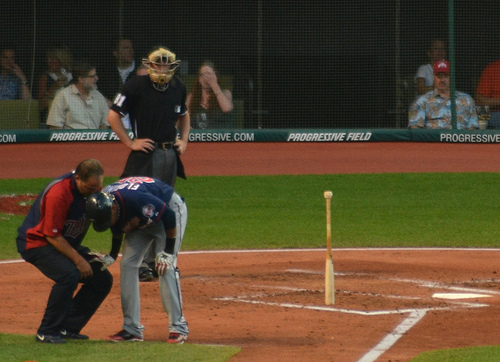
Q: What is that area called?
A: Baseball diamond.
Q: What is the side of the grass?
A: It's short.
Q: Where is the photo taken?
A: In a baseball field.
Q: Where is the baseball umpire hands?
A: On his hips.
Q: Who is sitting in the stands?
A: Spectators.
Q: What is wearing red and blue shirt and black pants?
A: The squatting man.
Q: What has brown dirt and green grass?
A: The baseball field.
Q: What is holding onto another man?
A: The man.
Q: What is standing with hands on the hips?
A: The man.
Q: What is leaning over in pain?
A: The baseball player.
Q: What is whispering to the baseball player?
A: The man.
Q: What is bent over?
A: The baseball player.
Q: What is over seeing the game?
A: The baseball umpire.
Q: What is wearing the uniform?
A: The baseball trainer.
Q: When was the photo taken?
A: Daytime.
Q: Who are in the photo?
A: Three men.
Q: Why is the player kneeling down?
A: Consulting the coach.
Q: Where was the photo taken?
A: Baseball field.